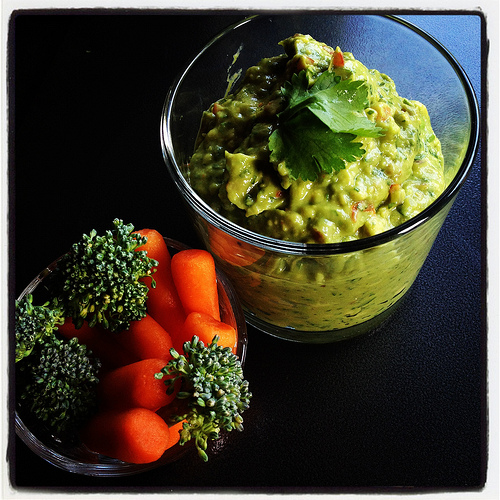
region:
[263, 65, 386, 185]
Garnish on top of guacamole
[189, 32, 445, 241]
Chunky guacamole in bowl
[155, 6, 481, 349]
Guacamole is sitting in a glass bowl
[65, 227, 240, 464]
Orange baby carrots in bowl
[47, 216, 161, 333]
Broccoli florets in bowl with carrots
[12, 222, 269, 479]
Broccoli and carrots in small glass bowl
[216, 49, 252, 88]
Guacamole smeared on side of bowl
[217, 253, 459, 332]
Texture of guacamole is liquified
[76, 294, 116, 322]
Broccoli leaves slightly discolored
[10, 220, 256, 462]
Broccoli and carrots are uncooked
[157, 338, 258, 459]
this is a cauliflower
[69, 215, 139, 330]
this is a cauliflower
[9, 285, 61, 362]
this is a cauliflower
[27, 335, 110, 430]
this is a cauliflower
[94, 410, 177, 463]
this is a carrot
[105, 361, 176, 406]
this is a carrot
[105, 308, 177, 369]
this is a carrot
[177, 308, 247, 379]
this is a carrot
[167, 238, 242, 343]
this is a carrot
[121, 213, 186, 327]
this is a carrot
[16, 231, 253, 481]
carrots in a glass pot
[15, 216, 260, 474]
carrots and broccoli in pot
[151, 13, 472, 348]
a glass of salad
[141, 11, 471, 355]
glass of salad on table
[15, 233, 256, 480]
a glass on table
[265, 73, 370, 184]
a piece of condiment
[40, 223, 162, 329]
a broccoli on top of carrot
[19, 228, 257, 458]
bunch of brocollis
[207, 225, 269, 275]
reflections of a carrot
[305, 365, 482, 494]
a black table top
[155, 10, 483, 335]
guacamole in a glass jar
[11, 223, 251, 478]
small bowl of carrots and broccoli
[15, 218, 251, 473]
raw broccoli florettes and baby carrots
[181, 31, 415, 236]
guacamole topped with cilantro leaves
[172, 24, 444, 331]
guacamole and cilantro in glass bowl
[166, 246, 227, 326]
one baby carrot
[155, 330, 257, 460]
green florette of broccoli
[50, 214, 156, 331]
small green broccoli florette top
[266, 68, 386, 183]
two green cilantro leaves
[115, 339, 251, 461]
orange carrots and green broccoli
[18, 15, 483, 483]
two glasses of food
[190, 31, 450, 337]
guacamole inside of glass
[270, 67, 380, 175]
two green leaves on guacamole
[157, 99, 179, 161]
light reflection on glass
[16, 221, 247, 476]
carrots and broccoli in glass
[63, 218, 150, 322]
floret on top of broccoli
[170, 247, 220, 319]
carrot with no skin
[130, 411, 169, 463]
top of baby carrot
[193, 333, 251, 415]
light reflection on floret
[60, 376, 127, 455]
darkness in between vegetables